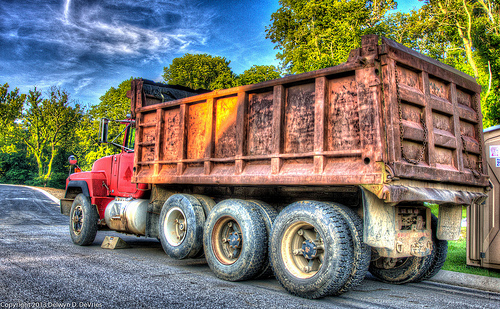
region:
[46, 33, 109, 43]
the sky is blue and visible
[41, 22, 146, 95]
the sky is blue and visible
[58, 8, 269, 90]
the sky is blue and visible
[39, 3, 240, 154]
the sky is blue and visible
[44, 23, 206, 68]
the sky is blue and visible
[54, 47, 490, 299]
a large dump trunk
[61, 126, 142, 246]
a red truck cab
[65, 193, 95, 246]
a front left truck tire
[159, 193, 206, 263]
a middle left truck tire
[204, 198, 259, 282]
a rear left truck tire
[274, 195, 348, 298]
a rear left truck tire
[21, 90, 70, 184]
a bright green tree in distance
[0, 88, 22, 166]
a bright green tree in distance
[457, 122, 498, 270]
a portable toilet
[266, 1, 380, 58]
a bright green tree in distance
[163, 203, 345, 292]
The back tires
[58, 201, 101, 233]
front tires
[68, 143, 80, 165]
A mirror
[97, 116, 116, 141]
a side mirror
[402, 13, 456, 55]
Green leaves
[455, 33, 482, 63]
A tree trunk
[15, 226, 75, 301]
The road is grey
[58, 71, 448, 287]
The truck is on the road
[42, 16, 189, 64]
the sky is cloudy and blue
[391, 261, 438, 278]
back tires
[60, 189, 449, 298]
the wheels on the truck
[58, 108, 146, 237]
the red part of the truck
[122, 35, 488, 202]
the bed of the truck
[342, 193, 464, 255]
the tire flaps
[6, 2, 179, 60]
the clouds in the sky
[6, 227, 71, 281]
the gray pavement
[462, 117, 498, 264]
the brown porta potty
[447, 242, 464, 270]
the grass near the truck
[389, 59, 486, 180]
the chains on the truck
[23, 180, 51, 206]
the curb on the road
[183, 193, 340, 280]
wheels on the ground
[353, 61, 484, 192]
back of the truck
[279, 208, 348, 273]
dirty wheel of truck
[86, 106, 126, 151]
rearview mirror on truck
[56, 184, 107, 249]
front wheel of truck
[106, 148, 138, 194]
door of the truck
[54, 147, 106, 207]
front of the truck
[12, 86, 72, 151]
trees in the distance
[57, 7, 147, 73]
sky above the ground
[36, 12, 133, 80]
clouds in the sky